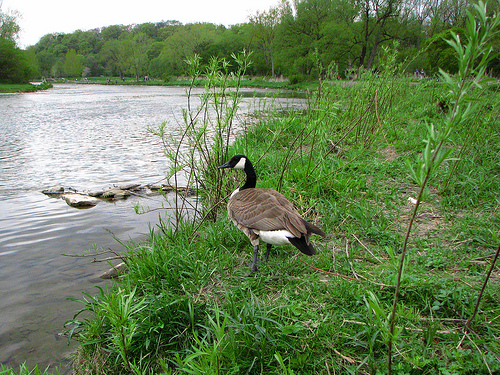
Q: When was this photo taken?
A: During the day.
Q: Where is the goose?
A: Standing along the riverbank.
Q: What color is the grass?
A: Green.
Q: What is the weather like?
A: Cloudy.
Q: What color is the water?
A: Brownish.